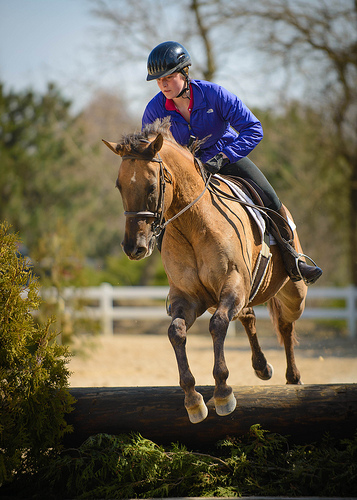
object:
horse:
[101, 115, 307, 424]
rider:
[141, 41, 323, 282]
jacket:
[140, 79, 263, 162]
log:
[0, 77, 355, 498]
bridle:
[151, 173, 212, 238]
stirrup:
[210, 174, 318, 304]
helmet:
[146, 41, 191, 82]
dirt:
[166, 297, 200, 402]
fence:
[20, 282, 357, 336]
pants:
[219, 155, 282, 213]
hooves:
[183, 395, 208, 424]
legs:
[168, 299, 197, 387]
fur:
[161, 214, 262, 268]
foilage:
[88, 433, 232, 496]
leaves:
[0, 83, 88, 246]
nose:
[119, 242, 147, 257]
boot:
[266, 206, 322, 282]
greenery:
[0, 432, 353, 496]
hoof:
[214, 387, 236, 416]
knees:
[168, 318, 188, 347]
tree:
[66, 383, 357, 446]